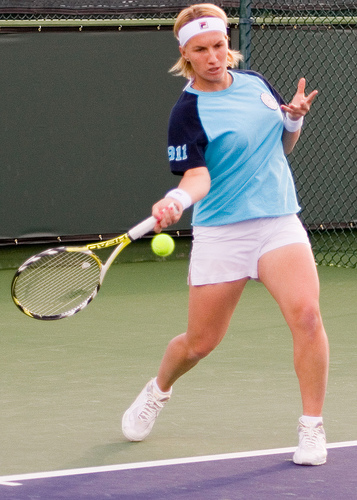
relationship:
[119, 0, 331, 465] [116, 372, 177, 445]
player wearing shoe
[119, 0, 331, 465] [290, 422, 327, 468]
player wearing shoe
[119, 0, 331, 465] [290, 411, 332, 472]
player wearing a shoe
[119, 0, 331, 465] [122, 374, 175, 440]
player wearing a shoe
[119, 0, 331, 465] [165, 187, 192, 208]
player wearing a wristband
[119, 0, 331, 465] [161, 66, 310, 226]
player wearing a shirt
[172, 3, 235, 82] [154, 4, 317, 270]
head on a tennis player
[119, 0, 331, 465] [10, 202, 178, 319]
player holding racquet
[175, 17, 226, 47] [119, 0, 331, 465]
headband worn by player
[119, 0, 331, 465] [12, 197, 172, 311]
player swinging racket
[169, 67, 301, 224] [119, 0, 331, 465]
shirt worn by player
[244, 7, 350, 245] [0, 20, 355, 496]
fence around court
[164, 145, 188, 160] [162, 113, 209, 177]
numbers on shirt sleeve